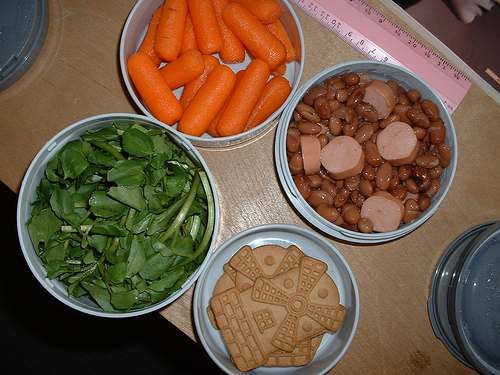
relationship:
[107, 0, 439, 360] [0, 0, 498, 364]
food on table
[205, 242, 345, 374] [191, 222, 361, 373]
cookies on plate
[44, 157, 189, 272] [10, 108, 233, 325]
greens in container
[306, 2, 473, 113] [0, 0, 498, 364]
ruler on table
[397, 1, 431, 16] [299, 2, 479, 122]
magazine behind ruler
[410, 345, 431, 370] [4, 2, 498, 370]
water spot on table top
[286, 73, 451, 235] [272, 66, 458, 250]
food in bowl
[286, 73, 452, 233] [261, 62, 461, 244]
beans in bowl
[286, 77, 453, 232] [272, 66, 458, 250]
beans in bowl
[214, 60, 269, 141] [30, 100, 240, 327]
carrots in dish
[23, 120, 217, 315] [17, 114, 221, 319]
food sticking off bowl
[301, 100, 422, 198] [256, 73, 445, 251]
food in bowl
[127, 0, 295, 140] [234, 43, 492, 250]
carrots in bowl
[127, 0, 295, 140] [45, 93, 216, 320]
carrots in bowl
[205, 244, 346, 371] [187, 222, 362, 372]
cookies in bowl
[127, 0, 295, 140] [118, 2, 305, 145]
carrots in bowl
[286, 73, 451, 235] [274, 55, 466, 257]
food in bowl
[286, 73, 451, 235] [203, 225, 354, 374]
food in bowl